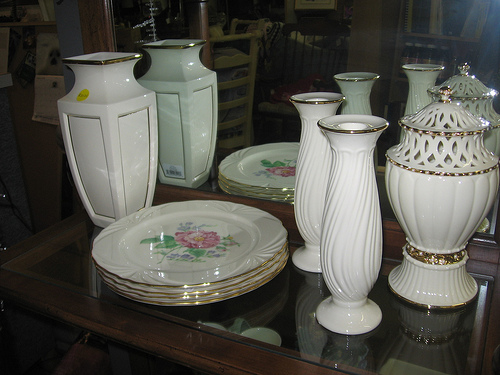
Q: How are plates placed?
A: Stacked.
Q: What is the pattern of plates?
A: Floral.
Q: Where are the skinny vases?
A: Right of plates.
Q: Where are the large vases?
A: Left of plates.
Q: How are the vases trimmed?
A: In gold.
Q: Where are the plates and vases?
A: Glass Top table.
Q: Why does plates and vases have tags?
A: They are for sale.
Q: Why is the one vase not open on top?
A: It has a lid.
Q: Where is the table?
A: Under the vases and plates.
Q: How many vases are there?
A: Three.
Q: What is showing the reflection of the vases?
A: The mirror.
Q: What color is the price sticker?
A: Yellow.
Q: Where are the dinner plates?
A: On the table.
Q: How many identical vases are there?
A: Two.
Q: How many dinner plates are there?
A: Four.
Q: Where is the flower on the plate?
A: In the center.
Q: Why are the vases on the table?
A: To be displayed.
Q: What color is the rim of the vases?
A: Gold.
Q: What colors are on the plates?
A: Pink, purple and green.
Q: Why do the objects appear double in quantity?
A: By mirror.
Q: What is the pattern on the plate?
A: Floral.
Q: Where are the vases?
A: On the table.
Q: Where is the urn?
A: On the table.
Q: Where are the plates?
A: On the table.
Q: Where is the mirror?
A: Behind the vases.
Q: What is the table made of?
A: Wood and glass.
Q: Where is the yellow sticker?
A: On the left most vase.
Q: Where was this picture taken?
A: Inside of a building.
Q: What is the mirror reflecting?
A: The store.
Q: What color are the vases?
A: White.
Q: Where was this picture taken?
A: At a sale or a store.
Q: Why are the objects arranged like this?
A: The objects are for sale.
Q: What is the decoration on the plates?
A: Flowers.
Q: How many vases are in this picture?
A: Three.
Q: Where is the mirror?
A: Behind the objects.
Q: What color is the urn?
A: White.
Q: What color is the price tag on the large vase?
A: Yellow.